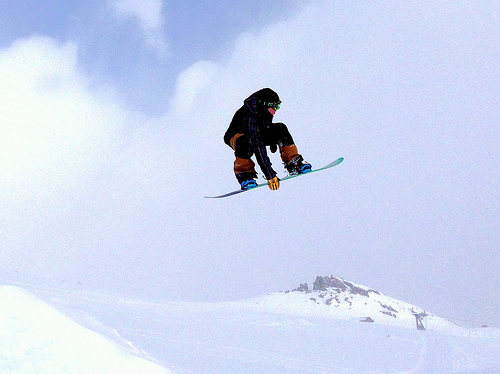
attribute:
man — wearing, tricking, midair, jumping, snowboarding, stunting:
[223, 86, 317, 190]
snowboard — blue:
[203, 155, 350, 200]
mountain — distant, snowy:
[278, 272, 465, 329]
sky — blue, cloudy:
[1, 2, 497, 249]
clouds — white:
[101, 0, 181, 63]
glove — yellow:
[268, 178, 281, 190]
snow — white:
[252, 289, 461, 332]